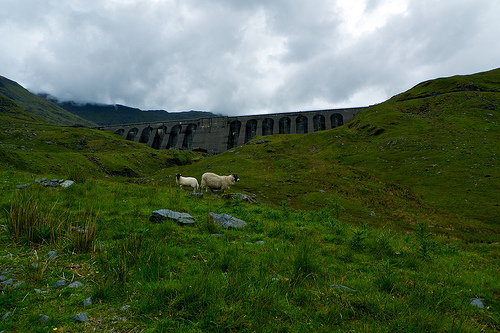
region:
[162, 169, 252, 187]
two sheep in field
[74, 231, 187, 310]
patch of green grass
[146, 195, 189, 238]
rock laying in field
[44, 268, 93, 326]
four rocks in field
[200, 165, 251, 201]
sheep looking to right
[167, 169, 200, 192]
sheep looking to left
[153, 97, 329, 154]
bridge in the background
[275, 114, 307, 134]
arches in the bridge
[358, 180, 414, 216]
variation the the color of grass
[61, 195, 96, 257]
tall pieces of grass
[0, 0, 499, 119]
gray cloudy skies over the grass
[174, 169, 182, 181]
the head of a sheep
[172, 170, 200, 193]
a sheep on the grass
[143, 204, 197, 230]
a gray rock on the grass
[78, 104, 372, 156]
a gray structure behind the grass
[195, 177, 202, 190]
the tail of a sheep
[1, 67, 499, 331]
a green grassy field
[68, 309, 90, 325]
a small gray rock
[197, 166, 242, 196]
a sheep on the grassy field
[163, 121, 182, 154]
a large archway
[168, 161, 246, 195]
Sheeps in the meadow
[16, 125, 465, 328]
Field cover with green grass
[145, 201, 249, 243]
Stones in middle of a field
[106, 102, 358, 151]
Bridge behind the hills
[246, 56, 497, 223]
Right hill is covered with green grass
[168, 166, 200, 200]
Head of sheep is black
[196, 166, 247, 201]
Sheep face to the right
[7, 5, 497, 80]
Sky is cloudy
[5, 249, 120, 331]
Small stones on the green grass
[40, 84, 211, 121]
Mountains behind the bridge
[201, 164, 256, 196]
A sheep standing in the grass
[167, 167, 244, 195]
two sheep standing in the grass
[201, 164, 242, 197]
A sheep facing right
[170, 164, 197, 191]
A sheep facing left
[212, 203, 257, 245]
A rock in the grass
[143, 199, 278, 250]
Two rocks in the grass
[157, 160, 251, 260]
Two sheep and two rocks in the grass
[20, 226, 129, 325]
Several rocks in grass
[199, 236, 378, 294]
Grass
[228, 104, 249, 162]
A arch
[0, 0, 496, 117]
a cloudy gray sky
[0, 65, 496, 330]
grassy green hills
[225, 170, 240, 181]
the head of a sheep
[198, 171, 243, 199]
a black and white sheep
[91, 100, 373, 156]
a large gray structure with arches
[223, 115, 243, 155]
a large arch in the gray structure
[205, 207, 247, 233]
a large rock on the grass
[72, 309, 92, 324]
a small rock on the grass